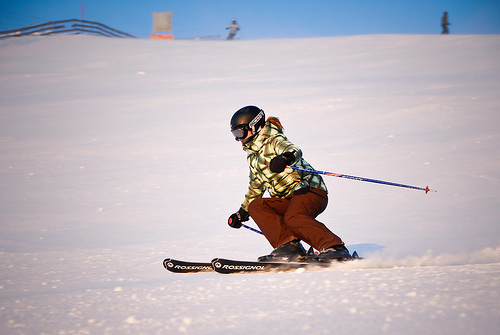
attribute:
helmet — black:
[230, 99, 266, 138]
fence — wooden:
[0, 18, 138, 38]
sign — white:
[150, 9, 174, 33]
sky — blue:
[0, 0, 497, 40]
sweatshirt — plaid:
[243, 116, 324, 204]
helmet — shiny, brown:
[227, 107, 266, 139]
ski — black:
[209, 257, 320, 276]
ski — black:
[161, 256, 221, 274]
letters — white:
[223, 259, 268, 271]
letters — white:
[172, 262, 211, 270]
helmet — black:
[230, 103, 268, 144]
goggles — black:
[231, 121, 250, 143]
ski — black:
[211, 258, 313, 271]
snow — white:
[180, 241, 493, 299]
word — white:
[172, 262, 212, 270]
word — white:
[220, 261, 265, 270]